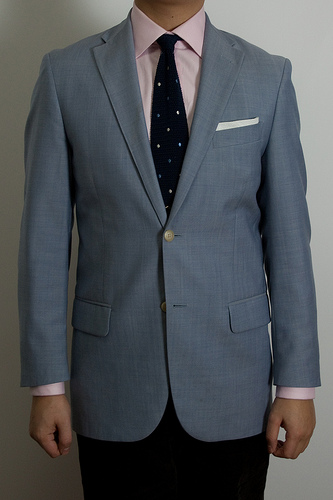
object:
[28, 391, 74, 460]
fist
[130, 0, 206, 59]
collar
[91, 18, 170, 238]
lapel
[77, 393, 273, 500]
pants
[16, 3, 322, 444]
jacket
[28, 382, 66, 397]
sleeve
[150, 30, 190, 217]
tie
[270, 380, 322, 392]
cuff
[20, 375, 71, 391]
cuff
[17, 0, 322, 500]
man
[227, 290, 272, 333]
foldedflap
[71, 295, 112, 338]
foldedflap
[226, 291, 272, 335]
flap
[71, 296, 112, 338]
flap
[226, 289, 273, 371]
pocket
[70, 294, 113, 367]
pocket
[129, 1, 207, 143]
shirt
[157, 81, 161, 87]
polka dot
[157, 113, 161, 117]
polka dot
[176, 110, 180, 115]
polka dot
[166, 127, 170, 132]
polka dot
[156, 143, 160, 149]
polka dot